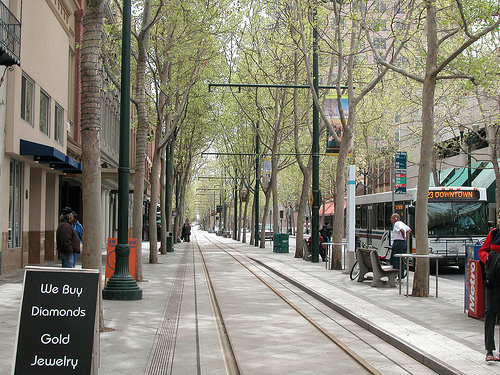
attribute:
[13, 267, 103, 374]
sign — black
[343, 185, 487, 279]
bus — white, moving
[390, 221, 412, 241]
shirt — white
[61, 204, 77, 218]
hat — dark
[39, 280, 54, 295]
letter — white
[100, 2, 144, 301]
pole — green, tall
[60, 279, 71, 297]
letter — white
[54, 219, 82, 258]
jacket — brown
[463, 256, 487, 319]
box — red, short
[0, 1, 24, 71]
balcony — black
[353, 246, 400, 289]
bench — gray, empty, vacant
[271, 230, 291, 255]
can — green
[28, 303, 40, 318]
letter — white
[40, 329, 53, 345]
letter — white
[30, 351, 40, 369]
letter — white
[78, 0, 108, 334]
tree trunk — tall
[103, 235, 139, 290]
sign — orange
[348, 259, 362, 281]
wheel — round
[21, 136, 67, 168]
awning — blue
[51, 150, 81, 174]
awning — blue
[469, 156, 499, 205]
awning — green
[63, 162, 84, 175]
awning — blue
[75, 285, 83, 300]
letter — white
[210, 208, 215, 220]
streetlight — red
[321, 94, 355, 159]
banner — hanging